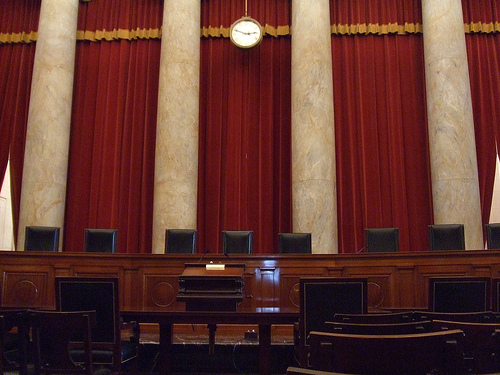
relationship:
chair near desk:
[55, 274, 121, 311] [120, 304, 289, 320]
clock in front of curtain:
[227, 17, 263, 50] [207, 49, 285, 222]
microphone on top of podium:
[196, 248, 212, 266] [177, 258, 247, 311]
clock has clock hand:
[227, 17, 263, 50] [232, 27, 246, 36]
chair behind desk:
[221, 229, 253, 254] [120, 304, 289, 320]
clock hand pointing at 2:
[247, 30, 263, 35] [255, 27, 258, 33]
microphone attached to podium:
[196, 248, 212, 266] [177, 258, 247, 311]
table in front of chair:
[120, 304, 289, 320] [55, 274, 121, 311]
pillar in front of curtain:
[152, 1, 200, 230] [207, 49, 285, 222]